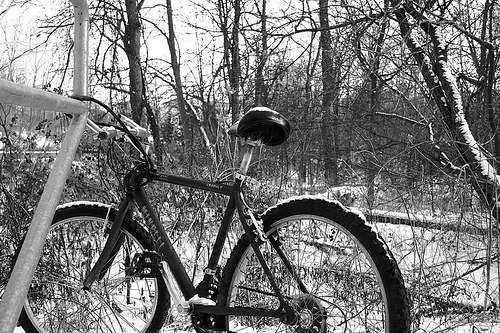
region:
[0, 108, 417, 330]
this is a bike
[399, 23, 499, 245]
this is a tree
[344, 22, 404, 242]
this is a tree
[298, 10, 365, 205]
this is a tree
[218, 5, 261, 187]
this is a tree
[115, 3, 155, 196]
this is a tree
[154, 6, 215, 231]
this is a tree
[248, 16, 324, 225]
this is a tree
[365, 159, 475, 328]
this is a tree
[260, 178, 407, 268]
The tire is snow covered.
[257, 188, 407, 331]
The tire is black.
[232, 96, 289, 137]
The seat has snow on it.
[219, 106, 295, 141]
The seat is black.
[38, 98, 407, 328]
The bike is black.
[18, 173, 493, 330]
The ground is snow covered.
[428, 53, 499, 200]
The branch is snow covered.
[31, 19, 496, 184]
The trees are bare.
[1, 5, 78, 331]
The bar is grey.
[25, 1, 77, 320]
The bar is metal.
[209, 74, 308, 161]
seat on the bike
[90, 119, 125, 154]
handlebar on the bike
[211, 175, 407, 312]
back tire of the bike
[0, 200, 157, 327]
front tire of the bike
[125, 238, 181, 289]
pedal on the bike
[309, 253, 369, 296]
spoke on back of bike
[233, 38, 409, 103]
trees in the distance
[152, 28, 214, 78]
sky in the background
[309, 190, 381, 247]
black tire of the bike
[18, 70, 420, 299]
black and white photo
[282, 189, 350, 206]
Snow resting on bike tire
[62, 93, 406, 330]
Bicycle with snow on it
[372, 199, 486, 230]
Fallen tree trunk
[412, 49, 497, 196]
Snow covered tree branch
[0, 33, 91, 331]
Metal poles next to bicycle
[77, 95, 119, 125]
Rope holding bicycle to metal pole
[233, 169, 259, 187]
Clamp holding bicycle seat in place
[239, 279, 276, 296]
Chain on side of bicycle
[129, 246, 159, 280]
Foot peddle on side of bicycle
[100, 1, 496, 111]
Row of bare trees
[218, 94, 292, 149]
The seat is snow covered.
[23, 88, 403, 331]
The bike is leaning.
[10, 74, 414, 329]
The bike is snow covered.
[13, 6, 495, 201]
The trees are snow covered.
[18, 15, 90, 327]
The pole is metal.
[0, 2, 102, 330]
The pole is silver.